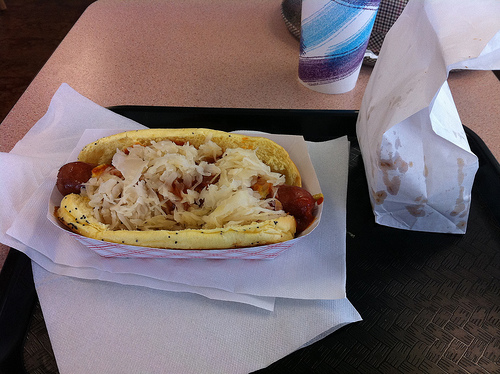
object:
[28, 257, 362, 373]
napkins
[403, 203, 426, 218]
grease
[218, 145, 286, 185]
sour kraut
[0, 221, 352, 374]
stack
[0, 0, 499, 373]
table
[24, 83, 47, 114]
speckled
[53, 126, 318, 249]
hot dog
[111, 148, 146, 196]
cooked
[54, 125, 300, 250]
bun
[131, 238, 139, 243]
seeds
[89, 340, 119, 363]
small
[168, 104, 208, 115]
small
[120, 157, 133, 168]
one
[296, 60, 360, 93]
bottom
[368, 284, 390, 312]
small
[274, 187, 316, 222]
right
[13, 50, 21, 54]
small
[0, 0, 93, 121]
floor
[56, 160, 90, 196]
left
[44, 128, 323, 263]
basket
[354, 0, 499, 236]
bag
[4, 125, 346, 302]
napkin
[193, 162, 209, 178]
sour kraut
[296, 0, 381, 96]
cup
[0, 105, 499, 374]
tray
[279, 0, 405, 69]
hat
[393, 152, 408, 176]
grease spot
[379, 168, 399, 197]
grease spot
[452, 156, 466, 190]
grease spot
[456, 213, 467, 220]
grease spot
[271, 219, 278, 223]
seed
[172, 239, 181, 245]
seed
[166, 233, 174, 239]
seed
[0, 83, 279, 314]
tissue